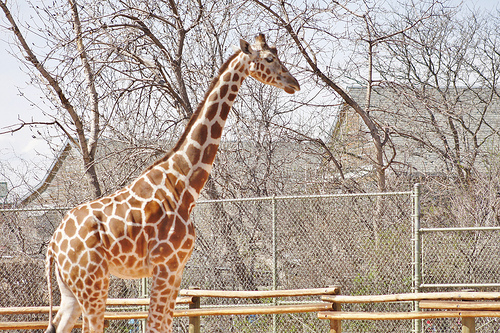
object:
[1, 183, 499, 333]
fence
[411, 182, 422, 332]
poles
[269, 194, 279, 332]
poles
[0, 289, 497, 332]
bleachers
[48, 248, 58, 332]
tail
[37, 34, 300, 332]
giraffe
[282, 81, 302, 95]
mouth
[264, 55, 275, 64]
eye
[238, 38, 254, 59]
ears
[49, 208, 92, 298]
hind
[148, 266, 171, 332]
legs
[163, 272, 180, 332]
legs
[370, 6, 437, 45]
branches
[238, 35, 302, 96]
head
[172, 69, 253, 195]
neck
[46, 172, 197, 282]
body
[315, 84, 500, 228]
house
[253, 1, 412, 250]
trees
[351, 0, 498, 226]
trees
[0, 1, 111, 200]
trees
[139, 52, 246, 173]
hair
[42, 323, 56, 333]
ball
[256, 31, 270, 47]
horn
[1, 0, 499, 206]
sky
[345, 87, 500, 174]
roof